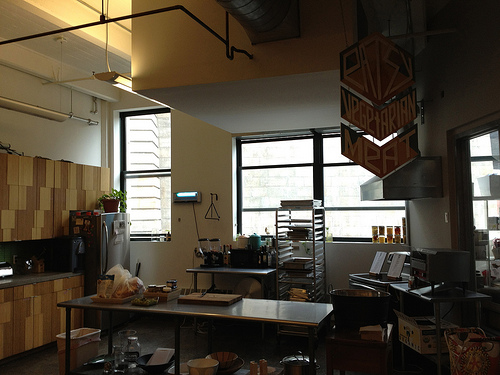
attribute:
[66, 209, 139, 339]
icebox — silver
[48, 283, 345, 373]
table — silver